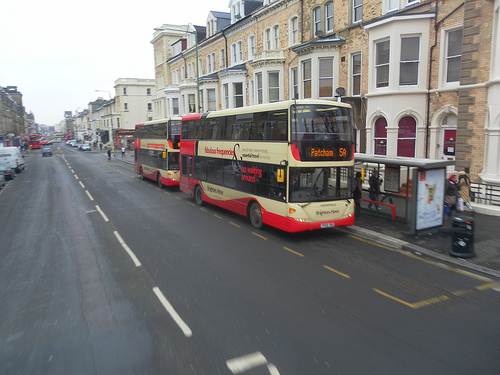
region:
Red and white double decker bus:
[179, 108, 357, 233]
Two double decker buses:
[132, 101, 362, 228]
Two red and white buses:
[132, 99, 354, 235]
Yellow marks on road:
[166, 179, 498, 321]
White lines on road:
[55, 142, 317, 374]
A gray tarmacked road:
[0, 155, 499, 371]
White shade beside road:
[353, 151, 452, 233]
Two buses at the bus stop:
[132, 97, 359, 235]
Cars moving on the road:
[28, 119, 96, 161]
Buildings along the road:
[58, 0, 499, 202]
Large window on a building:
[395, 31, 417, 103]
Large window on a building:
[367, 36, 399, 96]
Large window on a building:
[343, 52, 364, 101]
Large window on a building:
[308, 52, 340, 99]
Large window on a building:
[297, 58, 318, 93]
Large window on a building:
[282, 65, 304, 98]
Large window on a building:
[255, 68, 268, 103]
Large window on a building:
[435, 18, 468, 88]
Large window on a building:
[223, 37, 255, 62]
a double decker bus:
[169, 103, 360, 220]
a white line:
[148, 285, 210, 345]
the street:
[200, 283, 276, 323]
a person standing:
[363, 167, 389, 212]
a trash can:
[448, 219, 475, 256]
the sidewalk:
[483, 220, 499, 245]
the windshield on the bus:
[290, 173, 351, 198]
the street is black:
[17, 198, 89, 268]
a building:
[181, 45, 306, 100]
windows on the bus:
[202, 164, 259, 186]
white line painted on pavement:
[101, 225, 153, 276]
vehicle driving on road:
[33, 145, 61, 161]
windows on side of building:
[354, 27, 426, 101]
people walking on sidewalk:
[422, 162, 474, 229]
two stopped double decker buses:
[100, 88, 364, 255]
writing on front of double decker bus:
[303, 144, 353, 162]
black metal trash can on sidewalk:
[446, 212, 480, 261]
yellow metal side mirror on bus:
[272, 158, 288, 183]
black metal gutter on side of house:
[218, 26, 233, 66]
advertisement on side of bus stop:
[412, 167, 447, 231]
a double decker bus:
[178, 102, 358, 226]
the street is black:
[218, 267, 301, 330]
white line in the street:
[148, 286, 206, 337]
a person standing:
[369, 173, 382, 201]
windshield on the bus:
[295, 172, 351, 201]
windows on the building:
[398, 33, 428, 90]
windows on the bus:
[216, 119, 278, 139]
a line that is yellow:
[376, 282, 429, 314]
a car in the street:
[40, 144, 55, 157]